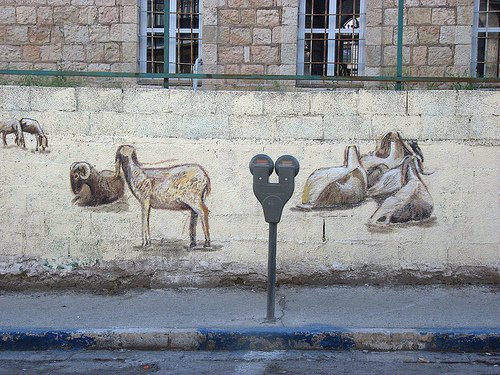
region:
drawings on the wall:
[72, 150, 216, 245]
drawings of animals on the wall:
[302, 138, 449, 234]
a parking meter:
[235, 152, 300, 324]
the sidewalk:
[82, 293, 172, 328]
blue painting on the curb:
[20, 328, 71, 345]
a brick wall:
[92, 95, 293, 135]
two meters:
[250, 155, 300, 180]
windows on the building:
[302, 0, 355, 75]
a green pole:
[72, 70, 145, 79]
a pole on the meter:
[265, 229, 282, 324]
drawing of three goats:
[301, 123, 446, 244]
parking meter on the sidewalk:
[240, 145, 300, 330]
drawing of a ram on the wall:
[62, 150, 119, 211]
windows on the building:
[126, 10, 201, 77]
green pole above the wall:
[19, 62, 121, 82]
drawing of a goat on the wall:
[116, 140, 217, 257]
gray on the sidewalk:
[85, 326, 193, 348]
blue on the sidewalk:
[210, 328, 341, 349]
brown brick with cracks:
[25, 22, 90, 57]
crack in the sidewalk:
[279, 289, 294, 325]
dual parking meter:
[245, 153, 298, 330]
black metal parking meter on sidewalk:
[237, 145, 308, 326]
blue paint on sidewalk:
[2, 318, 497, 358]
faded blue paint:
[2, 318, 102, 353]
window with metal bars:
[132, 2, 219, 93]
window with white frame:
[133, 3, 199, 93]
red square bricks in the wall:
[5, 4, 140, 83]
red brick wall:
[7, 2, 140, 64]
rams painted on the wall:
[58, 129, 227, 257]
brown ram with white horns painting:
[65, 150, 125, 216]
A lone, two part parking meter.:
[247, 148, 299, 325]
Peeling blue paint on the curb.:
[9, 325, 91, 355]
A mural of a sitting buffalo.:
[63, 159, 125, 208]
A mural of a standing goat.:
[107, 144, 224, 251]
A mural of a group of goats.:
[301, 125, 449, 239]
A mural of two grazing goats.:
[1, 117, 53, 155]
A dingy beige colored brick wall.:
[81, 93, 257, 139]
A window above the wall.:
[289, 0, 368, 81]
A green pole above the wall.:
[395, 2, 408, 86]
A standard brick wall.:
[16, 3, 125, 66]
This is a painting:
[102, 160, 198, 245]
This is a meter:
[229, 114, 316, 306]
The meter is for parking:
[260, 192, 315, 291]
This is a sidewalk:
[139, 305, 244, 363]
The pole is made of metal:
[254, 235, 314, 306]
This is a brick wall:
[293, 99, 335, 137]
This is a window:
[284, 4, 374, 86]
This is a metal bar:
[334, 26, 353, 98]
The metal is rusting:
[292, 22, 325, 37]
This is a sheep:
[86, 177, 181, 213]